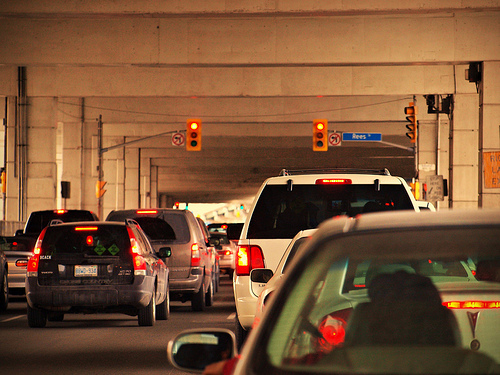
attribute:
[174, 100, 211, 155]
light — yellow, sign, red, green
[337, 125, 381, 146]
sign — blue, green, red, white, square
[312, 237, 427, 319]
car — square, stopped, gray, black, tunnel, grey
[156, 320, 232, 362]
mirror — on car, grey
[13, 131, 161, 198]
tunnel — here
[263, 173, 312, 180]
van — white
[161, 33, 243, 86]
bridge — grey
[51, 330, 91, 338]
road — grey, black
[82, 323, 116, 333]
line — white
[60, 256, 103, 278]
license plate — white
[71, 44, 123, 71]
stone — grey